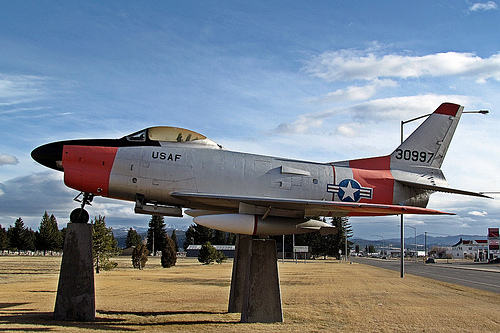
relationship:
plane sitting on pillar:
[32, 103, 495, 238] [52, 222, 100, 319]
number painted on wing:
[394, 148, 434, 166] [393, 99, 466, 177]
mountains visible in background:
[108, 222, 489, 247] [2, 209, 497, 282]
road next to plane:
[347, 254, 499, 293] [32, 103, 495, 238]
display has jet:
[22, 103, 495, 321] [32, 103, 495, 238]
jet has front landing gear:
[32, 103, 495, 238] [66, 191, 97, 223]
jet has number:
[32, 103, 495, 238] [394, 148, 434, 166]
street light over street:
[478, 106, 490, 116] [347, 254, 499, 293]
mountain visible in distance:
[115, 226, 145, 238] [3, 222, 492, 265]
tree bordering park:
[38, 213, 55, 258] [3, 255, 497, 330]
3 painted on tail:
[396, 149, 405, 162] [393, 99, 466, 177]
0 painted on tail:
[402, 148, 414, 160] [393, 99, 466, 177]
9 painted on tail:
[413, 149, 420, 162] [393, 99, 466, 177]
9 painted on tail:
[419, 150, 426, 164] [393, 99, 466, 177]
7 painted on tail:
[428, 150, 435, 163] [393, 99, 466, 177]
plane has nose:
[32, 103, 495, 238] [31, 142, 55, 169]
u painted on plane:
[153, 150, 160, 158] [32, 103, 495, 238]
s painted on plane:
[161, 151, 167, 160] [32, 103, 495, 238]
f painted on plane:
[174, 153, 183, 163] [32, 103, 495, 238]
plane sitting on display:
[32, 103, 495, 238] [22, 103, 495, 321]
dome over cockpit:
[127, 125, 204, 145] [125, 124, 219, 147]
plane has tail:
[32, 103, 495, 238] [393, 99, 466, 177]